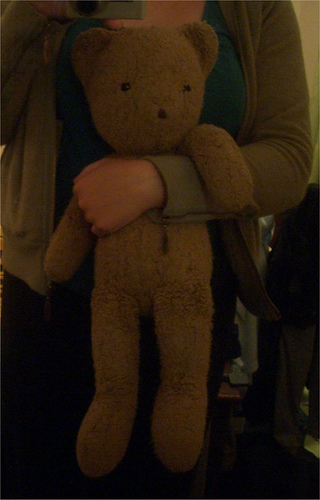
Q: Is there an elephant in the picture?
A: No, there are no elephants.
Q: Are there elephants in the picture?
A: No, there are no elephants.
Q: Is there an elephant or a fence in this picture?
A: No, there are no elephants or fences.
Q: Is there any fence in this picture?
A: No, there are no fences.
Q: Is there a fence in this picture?
A: No, there are no fences.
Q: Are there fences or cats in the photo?
A: No, there are no fences or cats.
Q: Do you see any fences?
A: No, there are no fences.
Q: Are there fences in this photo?
A: No, there are no fences.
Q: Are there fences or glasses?
A: No, there are no fences or glasses.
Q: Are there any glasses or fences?
A: No, there are no fences or glasses.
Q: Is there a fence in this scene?
A: No, there are no fences.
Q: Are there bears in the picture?
A: Yes, there is a bear.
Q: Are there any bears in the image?
A: Yes, there is a bear.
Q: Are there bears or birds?
A: Yes, there is a bear.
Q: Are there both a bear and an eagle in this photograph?
A: No, there is a bear but no eagles.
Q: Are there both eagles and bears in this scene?
A: No, there is a bear but no eagles.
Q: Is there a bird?
A: No, there are no birds.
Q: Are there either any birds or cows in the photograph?
A: No, there are no birds or cows.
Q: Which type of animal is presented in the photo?
A: The animal is a bear.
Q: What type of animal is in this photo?
A: The animal is a bear.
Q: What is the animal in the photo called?
A: The animal is a bear.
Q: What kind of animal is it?
A: The animal is a bear.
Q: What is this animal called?
A: This is a bear.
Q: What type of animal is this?
A: This is a bear.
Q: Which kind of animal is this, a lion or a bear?
A: This is a bear.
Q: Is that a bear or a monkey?
A: That is a bear.